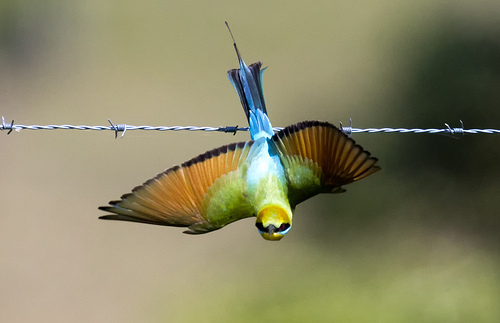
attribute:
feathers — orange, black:
[106, 167, 234, 229]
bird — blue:
[125, 47, 381, 261]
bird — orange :
[148, 51, 371, 233]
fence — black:
[20, 101, 197, 138]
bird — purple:
[121, 71, 388, 237]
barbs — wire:
[4, 117, 124, 137]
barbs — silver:
[4, 110, 152, 134]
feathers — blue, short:
[214, 25, 274, 116]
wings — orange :
[97, 118, 388, 218]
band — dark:
[248, 212, 293, 232]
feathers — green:
[204, 163, 315, 217]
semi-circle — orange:
[248, 202, 288, 235]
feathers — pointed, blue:
[246, 105, 271, 136]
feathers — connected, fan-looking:
[98, 143, 248, 223]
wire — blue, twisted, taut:
[2, 115, 496, 137]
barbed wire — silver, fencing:
[4, 110, 498, 146]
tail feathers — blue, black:
[223, 61, 270, 114]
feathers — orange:
[148, 160, 210, 210]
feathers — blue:
[250, 134, 280, 167]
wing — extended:
[96, 150, 235, 244]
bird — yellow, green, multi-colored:
[100, 45, 407, 239]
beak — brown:
[258, 226, 278, 237]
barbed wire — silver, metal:
[1, 114, 498, 138]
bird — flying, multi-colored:
[74, 22, 379, 250]